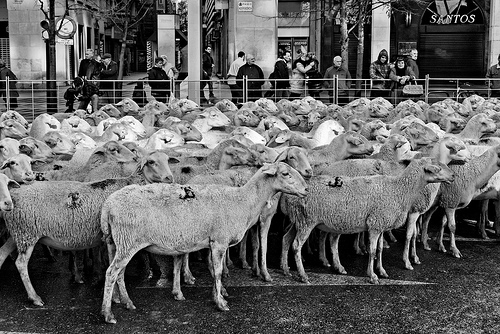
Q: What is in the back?
A: Pillars.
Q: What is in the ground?
A: Sheep.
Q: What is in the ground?
A: Sheeps.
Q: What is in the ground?
A: Sheeps.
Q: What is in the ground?
A: Fence.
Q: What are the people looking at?
A: Sheep.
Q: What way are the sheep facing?
A: To the right.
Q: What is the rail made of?
A: Metal.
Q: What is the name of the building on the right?
A: Santos.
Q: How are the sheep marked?
A: They are branded.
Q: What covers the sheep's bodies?
A: Fur.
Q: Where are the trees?
A: On the sidewalk.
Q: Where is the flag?
A: On the side of the building.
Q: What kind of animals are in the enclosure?
A: Sheep.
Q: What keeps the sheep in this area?
A: Fence.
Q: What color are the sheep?
A: White.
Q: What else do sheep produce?
A: Lambs.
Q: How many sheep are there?
A: Over 50.